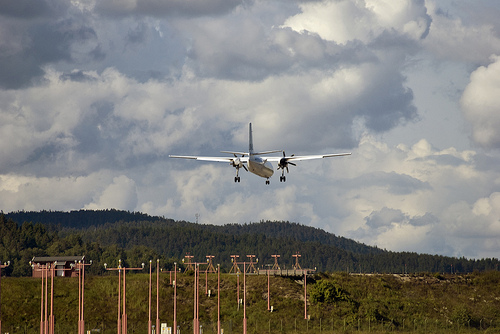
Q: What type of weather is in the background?
A: It is cloudy.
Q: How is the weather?
A: It is cloudy.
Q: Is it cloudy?
A: Yes, it is cloudy.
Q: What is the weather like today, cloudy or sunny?
A: It is cloudy.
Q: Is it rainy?
A: No, it is cloudy.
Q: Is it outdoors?
A: Yes, it is outdoors.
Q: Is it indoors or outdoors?
A: It is outdoors.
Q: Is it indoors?
A: No, it is outdoors.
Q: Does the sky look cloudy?
A: Yes, the sky is cloudy.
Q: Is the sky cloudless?
A: No, the sky is cloudy.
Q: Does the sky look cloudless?
A: No, the sky is cloudy.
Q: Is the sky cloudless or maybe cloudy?
A: The sky is cloudy.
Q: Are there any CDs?
A: No, there are no cds.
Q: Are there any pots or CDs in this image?
A: No, there are no CDs or pots.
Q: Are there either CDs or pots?
A: No, there are no CDs or pots.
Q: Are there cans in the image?
A: No, there are no cans.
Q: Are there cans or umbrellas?
A: No, there are no cans or umbrellas.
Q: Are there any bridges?
A: Yes, there is a bridge.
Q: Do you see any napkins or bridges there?
A: Yes, there is a bridge.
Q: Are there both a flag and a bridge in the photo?
A: No, there is a bridge but no flags.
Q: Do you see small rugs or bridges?
A: Yes, there is a small bridge.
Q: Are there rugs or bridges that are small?
A: Yes, the bridge is small.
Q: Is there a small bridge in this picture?
A: Yes, there is a small bridge.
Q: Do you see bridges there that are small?
A: Yes, there is a bridge that is small.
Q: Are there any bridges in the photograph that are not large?
A: Yes, there is a small bridge.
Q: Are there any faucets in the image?
A: No, there are no faucets.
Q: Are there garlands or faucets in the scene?
A: No, there are no faucets or garlands.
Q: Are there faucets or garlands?
A: No, there are no faucets or garlands.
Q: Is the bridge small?
A: Yes, the bridge is small.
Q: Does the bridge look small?
A: Yes, the bridge is small.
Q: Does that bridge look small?
A: Yes, the bridge is small.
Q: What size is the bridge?
A: The bridge is small.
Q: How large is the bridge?
A: The bridge is small.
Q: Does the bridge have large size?
A: No, the bridge is small.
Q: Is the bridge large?
A: No, the bridge is small.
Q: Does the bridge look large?
A: No, the bridge is small.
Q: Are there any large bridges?
A: No, there is a bridge but it is small.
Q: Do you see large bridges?
A: No, there is a bridge but it is small.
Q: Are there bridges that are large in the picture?
A: No, there is a bridge but it is small.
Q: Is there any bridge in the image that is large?
A: No, there is a bridge but it is small.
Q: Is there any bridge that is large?
A: No, there is a bridge but it is small.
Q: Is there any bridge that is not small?
A: No, there is a bridge but it is small.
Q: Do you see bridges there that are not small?
A: No, there is a bridge but it is small.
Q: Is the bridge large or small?
A: The bridge is small.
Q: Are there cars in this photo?
A: No, there are no cars.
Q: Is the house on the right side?
A: No, the house is on the left of the image.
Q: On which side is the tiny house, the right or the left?
A: The house is on the left of the image.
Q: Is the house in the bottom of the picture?
A: Yes, the house is in the bottom of the image.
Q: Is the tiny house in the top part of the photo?
A: No, the house is in the bottom of the image.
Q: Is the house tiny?
A: Yes, the house is tiny.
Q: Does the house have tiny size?
A: Yes, the house is tiny.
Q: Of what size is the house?
A: The house is tiny.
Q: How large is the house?
A: The house is tiny.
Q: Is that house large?
A: No, the house is tiny.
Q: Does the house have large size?
A: No, the house is tiny.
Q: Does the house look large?
A: No, the house is tiny.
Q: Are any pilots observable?
A: No, there are no pilots.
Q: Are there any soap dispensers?
A: No, there are no soap dispensers.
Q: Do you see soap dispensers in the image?
A: No, there are no soap dispensers.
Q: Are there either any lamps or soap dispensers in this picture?
A: No, there are no soap dispensers or lamps.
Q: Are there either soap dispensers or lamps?
A: No, there are no soap dispensers or lamps.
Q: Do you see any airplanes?
A: Yes, there is an airplane.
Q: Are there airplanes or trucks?
A: Yes, there is an airplane.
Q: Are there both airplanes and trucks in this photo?
A: No, there is an airplane but no trucks.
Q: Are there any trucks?
A: No, there are no trucks.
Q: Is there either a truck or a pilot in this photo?
A: No, there are no trucks or pilots.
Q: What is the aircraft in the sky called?
A: The aircraft is an airplane.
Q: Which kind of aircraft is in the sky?
A: The aircraft is an airplane.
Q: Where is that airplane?
A: The airplane is in the sky.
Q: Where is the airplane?
A: The airplane is in the sky.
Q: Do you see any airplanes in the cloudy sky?
A: Yes, there is an airplane in the sky.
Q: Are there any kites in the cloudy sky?
A: No, there is an airplane in the sky.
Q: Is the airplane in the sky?
A: Yes, the airplane is in the sky.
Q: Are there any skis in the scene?
A: No, there are no skis.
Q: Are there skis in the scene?
A: No, there are no skis.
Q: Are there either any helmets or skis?
A: No, there are no skis or helmets.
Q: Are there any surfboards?
A: No, there are no surfboards.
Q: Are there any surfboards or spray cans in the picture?
A: No, there are no surfboards or spray cans.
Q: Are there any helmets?
A: No, there are no helmets.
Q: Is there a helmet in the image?
A: No, there are no helmets.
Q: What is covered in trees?
A: The hill is covered in trees.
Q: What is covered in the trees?
A: The hill is covered in trees.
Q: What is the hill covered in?
A: The hill is covered in trees.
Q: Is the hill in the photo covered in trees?
A: Yes, the hill is covered in trees.